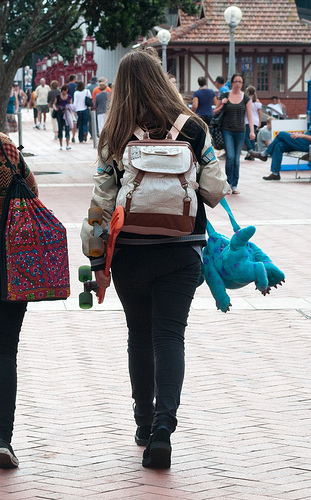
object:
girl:
[80, 45, 230, 470]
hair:
[94, 50, 210, 165]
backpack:
[116, 113, 198, 236]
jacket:
[81, 113, 230, 272]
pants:
[110, 245, 201, 429]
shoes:
[134, 426, 152, 446]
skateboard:
[78, 204, 125, 309]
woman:
[213, 74, 256, 195]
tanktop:
[218, 91, 250, 132]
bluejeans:
[222, 130, 246, 191]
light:
[223, 4, 243, 24]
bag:
[202, 198, 286, 314]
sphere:
[157, 29, 170, 42]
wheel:
[79, 290, 93, 309]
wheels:
[78, 265, 93, 283]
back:
[152, 431, 171, 449]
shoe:
[142, 427, 172, 468]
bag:
[5, 173, 71, 303]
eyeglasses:
[232, 80, 243, 83]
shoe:
[35, 124, 41, 130]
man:
[34, 78, 51, 130]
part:
[229, 32, 235, 46]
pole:
[228, 23, 238, 82]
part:
[297, 158, 302, 171]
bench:
[283, 145, 311, 180]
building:
[131, 1, 309, 120]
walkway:
[24, 314, 124, 499]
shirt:
[55, 94, 72, 106]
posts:
[81, 33, 97, 86]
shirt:
[73, 89, 91, 112]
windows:
[271, 54, 288, 94]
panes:
[257, 76, 265, 85]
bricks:
[194, 315, 301, 464]